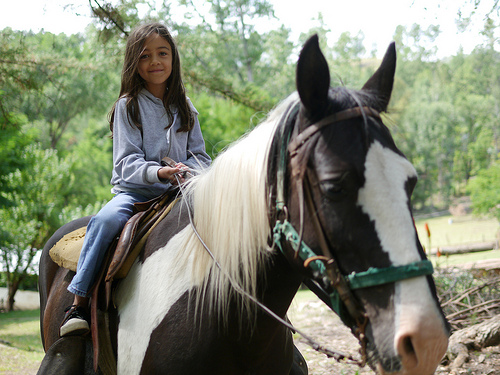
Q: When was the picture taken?
A: Daytime.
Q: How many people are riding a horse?
A: One.